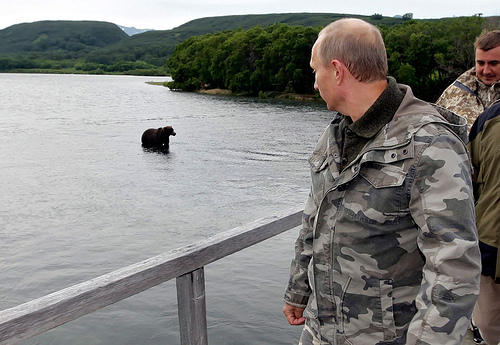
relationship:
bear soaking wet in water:
[142, 126, 177, 155] [187, 194, 265, 215]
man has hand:
[280, 18, 479, 345] [263, 281, 318, 338]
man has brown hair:
[437, 28, 499, 130] [472, 29, 498, 54]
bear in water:
[142, 126, 177, 155] [1, 71, 440, 345]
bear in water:
[139, 125, 177, 157] [5, 64, 408, 345]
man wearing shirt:
[280, 18, 479, 345] [331, 96, 404, 153]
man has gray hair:
[280, 18, 479, 345] [303, 6, 393, 79]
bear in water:
[139, 125, 177, 157] [2, 72, 337, 343]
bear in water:
[142, 126, 177, 155] [4, 74, 324, 280]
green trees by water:
[1, 13, 499, 104] [2, 72, 337, 343]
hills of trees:
[0, 11, 500, 91] [4, 19, 121, 73]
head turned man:
[307, 17, 391, 114] [280, 18, 479, 345]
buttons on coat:
[328, 147, 411, 169] [282, 83, 483, 345]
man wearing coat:
[437, 28, 500, 131] [438, 72, 498, 134]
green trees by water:
[0, 12, 500, 100] [2, 72, 337, 343]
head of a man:
[303, 12, 392, 117] [280, 15, 479, 344]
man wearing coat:
[437, 28, 500, 131] [435, 66, 500, 134]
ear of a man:
[331, 58, 344, 85] [280, 18, 479, 345]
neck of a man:
[336, 74, 389, 124] [280, 18, 479, 345]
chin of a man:
[326, 100, 347, 112] [280, 15, 479, 344]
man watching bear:
[280, 15, 479, 344] [142, 126, 177, 155]